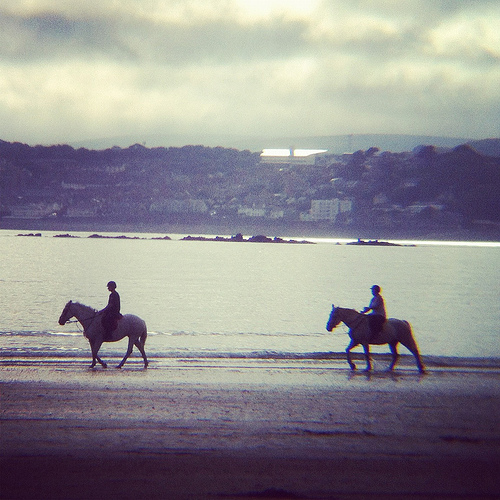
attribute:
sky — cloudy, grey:
[1, 0, 498, 150]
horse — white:
[60, 300, 153, 372]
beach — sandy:
[3, 360, 498, 498]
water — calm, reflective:
[0, 228, 499, 353]